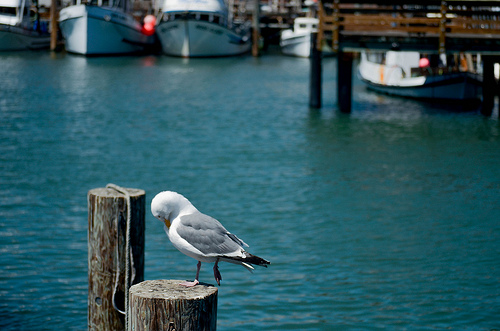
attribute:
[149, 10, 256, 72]
boat — green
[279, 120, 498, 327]
water — greenish, blue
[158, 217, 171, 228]
beak — orange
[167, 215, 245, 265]
wings — grey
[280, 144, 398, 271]
blue water — greenish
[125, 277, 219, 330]
post — wooden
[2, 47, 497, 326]
river — blue, greenish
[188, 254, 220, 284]
foot — up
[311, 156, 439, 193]
water — dark green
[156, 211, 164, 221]
eye — black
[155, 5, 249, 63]
boat — white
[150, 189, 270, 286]
seagull — gray, white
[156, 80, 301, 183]
blue water — greenish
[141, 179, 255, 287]
bird — gray, white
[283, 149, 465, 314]
water — greenish, blue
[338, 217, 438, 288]
water — dark green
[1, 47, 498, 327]
water — dark green, blue